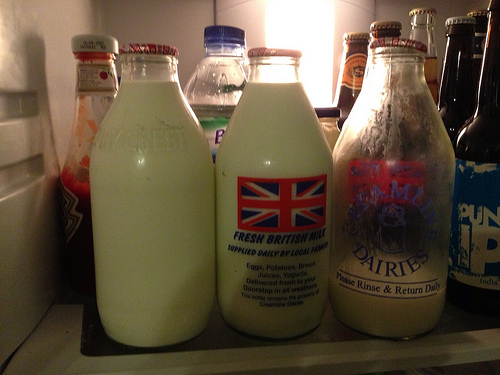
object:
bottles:
[88, 38, 334, 349]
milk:
[89, 77, 212, 348]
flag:
[233, 176, 326, 230]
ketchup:
[57, 25, 119, 259]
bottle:
[437, 14, 475, 145]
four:
[437, 7, 496, 143]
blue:
[201, 24, 247, 49]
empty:
[334, 38, 446, 281]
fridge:
[2, 4, 492, 372]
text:
[231, 228, 326, 252]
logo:
[221, 229, 329, 310]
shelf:
[30, 338, 499, 374]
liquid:
[90, 80, 214, 346]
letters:
[240, 260, 321, 314]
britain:
[233, 233, 320, 245]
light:
[262, 4, 336, 105]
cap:
[199, 24, 247, 55]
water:
[180, 24, 247, 160]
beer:
[413, 3, 498, 310]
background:
[0, 0, 497, 99]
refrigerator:
[1, 1, 64, 310]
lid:
[364, 38, 429, 55]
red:
[119, 44, 181, 54]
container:
[183, 53, 238, 117]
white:
[452, 202, 492, 290]